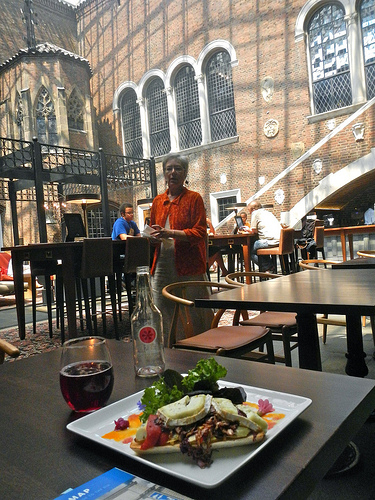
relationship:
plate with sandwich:
[62, 368, 315, 490] [133, 367, 262, 466]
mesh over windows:
[210, 71, 230, 109] [104, 41, 253, 161]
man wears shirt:
[102, 203, 166, 241] [106, 213, 139, 238]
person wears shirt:
[140, 151, 214, 349] [144, 185, 210, 267]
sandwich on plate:
[110, 357, 270, 457] [66, 363, 323, 481]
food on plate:
[100, 354, 286, 470] [62, 368, 315, 490]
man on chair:
[246, 199, 282, 267] [257, 228, 296, 266]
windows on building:
[115, 32, 251, 172] [0, 1, 375, 259]